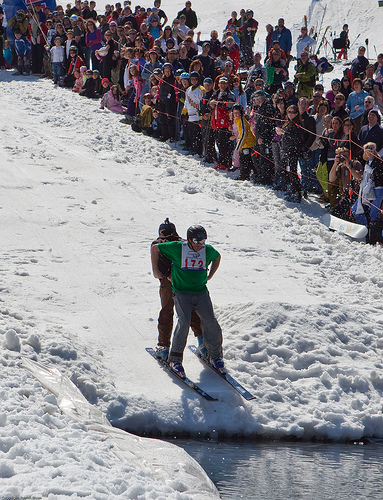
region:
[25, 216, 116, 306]
A heap of white snow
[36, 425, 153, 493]
A heap of white snow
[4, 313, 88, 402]
A heap of white snow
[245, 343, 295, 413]
A heap of white snow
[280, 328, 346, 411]
A heap of white snow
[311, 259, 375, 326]
A heap of white snow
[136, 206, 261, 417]
men playing skate game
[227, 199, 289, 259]
A heap of white snow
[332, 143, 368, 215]
A man taking a photo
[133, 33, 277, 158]
A crowd of people spectating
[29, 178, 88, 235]
this is the ground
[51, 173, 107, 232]
the ground has snow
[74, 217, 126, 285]
this is the snow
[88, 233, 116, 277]
the snow is white in color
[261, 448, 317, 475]
this is the water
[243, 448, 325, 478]
the water has ripples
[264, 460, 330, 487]
the ripples are big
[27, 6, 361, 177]
these are some people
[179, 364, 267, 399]
these are snowboards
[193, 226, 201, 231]
the helmet is black in color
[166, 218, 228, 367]
this is a man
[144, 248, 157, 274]
the man is light skinned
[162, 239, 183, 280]
this is a t shirt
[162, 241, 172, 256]
the t shirt is green in color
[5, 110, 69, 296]
this is the snow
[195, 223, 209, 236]
this is a helmet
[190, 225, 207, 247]
the helmet is black in color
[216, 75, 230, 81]
this is a cap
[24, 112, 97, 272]
the snow is white in color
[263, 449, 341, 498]
this is a water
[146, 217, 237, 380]
man in green shirt skiing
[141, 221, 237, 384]
man in green shirt holding person behind him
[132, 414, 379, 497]
small portion of water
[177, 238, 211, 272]
mans bib reads 172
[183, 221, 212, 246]
man wearing a black helmet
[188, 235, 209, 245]
man wearing mirrored sunglasses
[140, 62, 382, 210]
rope dividing crowd and event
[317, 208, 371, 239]
snowboard lying on ground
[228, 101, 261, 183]
boy wearing yellow jacket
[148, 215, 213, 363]
man wearing brown on skis